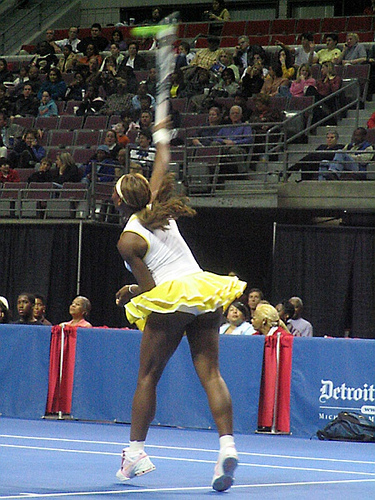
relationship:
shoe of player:
[209, 430, 242, 493] [112, 109, 248, 496]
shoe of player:
[115, 440, 156, 483] [112, 109, 248, 496]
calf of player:
[208, 374, 228, 414] [112, 109, 248, 496]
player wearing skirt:
[112, 109, 248, 496] [121, 272, 253, 328]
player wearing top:
[112, 109, 248, 496] [116, 205, 201, 288]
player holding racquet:
[112, 109, 248, 496] [146, 13, 184, 126]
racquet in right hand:
[146, 13, 184, 126] [136, 102, 193, 161]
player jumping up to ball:
[112, 109, 248, 496] [130, 20, 155, 39]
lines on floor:
[0, 433, 374, 498] [1, 415, 371, 498]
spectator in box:
[247, 301, 287, 336] [1, 322, 369, 430]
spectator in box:
[216, 297, 254, 335] [1, 322, 369, 430]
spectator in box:
[285, 295, 313, 336] [1, 322, 369, 430]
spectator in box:
[54, 294, 92, 325] [1, 322, 369, 430]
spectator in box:
[6, 291, 39, 325] [1, 322, 369, 430]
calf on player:
[208, 374, 232, 416] [103, 169, 234, 478]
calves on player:
[133, 385, 153, 439] [103, 169, 234, 478]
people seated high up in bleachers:
[0, 22, 375, 178] [0, 1, 374, 221]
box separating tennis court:
[0, 320, 374, 439] [0, 413, 374, 498]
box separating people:
[0, 320, 374, 439] [0, 1, 374, 181]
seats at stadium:
[0, 13, 373, 215] [0, 0, 373, 498]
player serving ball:
[112, 109, 248, 496] [130, 25, 169, 38]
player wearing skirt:
[112, 109, 248, 496] [108, 249, 285, 355]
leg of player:
[126, 309, 193, 441] [112, 109, 248, 496]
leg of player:
[183, 317, 235, 435] [112, 109, 248, 496]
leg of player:
[130, 309, 187, 441] [112, 109, 248, 496]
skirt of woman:
[123, 269, 250, 333] [106, 139, 232, 479]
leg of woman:
[130, 309, 187, 441] [94, 152, 285, 356]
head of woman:
[100, 172, 151, 216] [85, 19, 255, 498]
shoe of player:
[212, 434, 238, 492] [112, 109, 248, 496]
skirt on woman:
[121, 266, 250, 334] [106, 14, 248, 494]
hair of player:
[115, 171, 196, 232] [112, 109, 248, 496]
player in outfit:
[112, 109, 248, 496] [109, 194, 252, 341]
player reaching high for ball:
[85, 170, 252, 478] [130, 19, 157, 38]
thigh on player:
[134, 303, 198, 379] [112, 109, 248, 496]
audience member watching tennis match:
[322, 125, 372, 179] [1, 34, 373, 498]